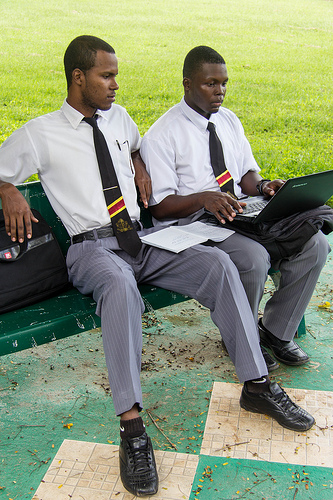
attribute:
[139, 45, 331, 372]
man — sitting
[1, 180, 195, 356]
bench — green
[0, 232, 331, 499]
concrete — green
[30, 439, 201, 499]
square — tiled, white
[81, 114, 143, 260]
tie — black, striped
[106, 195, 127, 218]
stripe — red, yellow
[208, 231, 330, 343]
pants — striped, gray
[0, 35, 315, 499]
man — sitting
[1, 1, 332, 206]
field — grassy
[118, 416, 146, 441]
sock — black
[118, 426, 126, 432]
emblem — white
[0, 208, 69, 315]
bag — black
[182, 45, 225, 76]
hair — short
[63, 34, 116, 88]
hair — short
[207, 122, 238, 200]
tie — black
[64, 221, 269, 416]
pants — striped, gray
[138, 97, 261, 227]
shirt — white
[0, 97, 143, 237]
shirt — white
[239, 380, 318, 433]
shoe — black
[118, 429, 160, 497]
shoe — black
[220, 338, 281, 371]
shoe — black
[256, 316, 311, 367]
shoe — black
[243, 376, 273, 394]
sock — black